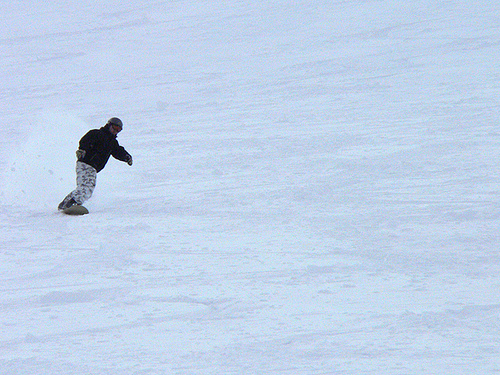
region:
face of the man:
[96, 100, 145, 157]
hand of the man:
[116, 146, 141, 166]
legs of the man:
[46, 160, 105, 195]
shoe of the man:
[41, 193, 98, 228]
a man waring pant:
[66, 170, 123, 219]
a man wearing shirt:
[69, 125, 129, 169]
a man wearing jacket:
[58, 102, 149, 194]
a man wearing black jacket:
[82, 115, 132, 168]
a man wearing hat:
[103, 104, 144, 162]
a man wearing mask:
[96, 108, 145, 145]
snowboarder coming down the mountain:
[53, 104, 137, 221]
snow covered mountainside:
[0, 8, 493, 368]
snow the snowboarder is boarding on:
[2, 8, 489, 363]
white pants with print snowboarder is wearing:
[70, 162, 95, 200]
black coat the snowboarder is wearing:
[80, 123, 125, 175]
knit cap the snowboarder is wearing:
[111, 117, 124, 131]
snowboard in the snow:
[56, 202, 90, 217]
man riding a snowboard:
[61, 117, 134, 214]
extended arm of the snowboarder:
[115, 141, 138, 177]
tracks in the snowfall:
[15, 124, 342, 294]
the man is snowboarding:
[53, 106, 136, 223]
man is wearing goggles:
[107, 119, 124, 133]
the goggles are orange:
[111, 122, 125, 132]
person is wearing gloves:
[72, 143, 139, 169]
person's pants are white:
[68, 160, 97, 207]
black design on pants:
[64, 164, 99, 204]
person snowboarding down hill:
[51, 111, 133, 216]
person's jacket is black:
[76, 121, 131, 169]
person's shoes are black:
[55, 195, 81, 210]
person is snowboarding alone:
[49, 109, 136, 219]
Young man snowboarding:
[50, 101, 145, 227]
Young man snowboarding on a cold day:
[50, 105, 155, 230]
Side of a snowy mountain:
[266, 56, 446, 266]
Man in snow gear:
[45, 102, 150, 222]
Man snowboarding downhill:
[35, 86, 175, 256]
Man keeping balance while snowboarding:
[45, 100, 180, 242]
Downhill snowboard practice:
[40, 86, 190, 256]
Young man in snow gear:
[26, 92, 213, 257]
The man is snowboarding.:
[49, 100, 144, 223]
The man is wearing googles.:
[108, 121, 128, 136]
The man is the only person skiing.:
[42, 70, 159, 225]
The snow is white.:
[178, 165, 253, 241]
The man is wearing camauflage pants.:
[59, 162, 102, 214]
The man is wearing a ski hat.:
[99, 110, 131, 138]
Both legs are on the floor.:
[54, 183, 91, 220]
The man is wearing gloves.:
[120, 152, 142, 174]